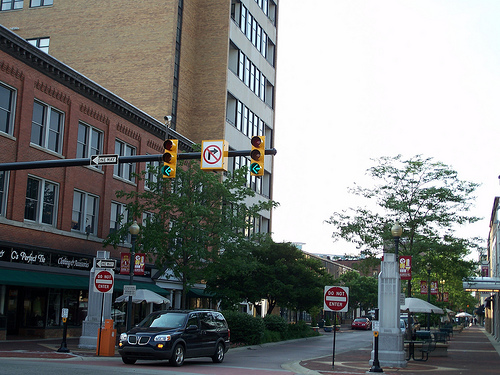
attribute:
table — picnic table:
[404, 337, 431, 364]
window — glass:
[113, 136, 123, 177]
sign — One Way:
[95, 151, 135, 172]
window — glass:
[0, 78, 20, 139]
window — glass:
[22, 87, 85, 151]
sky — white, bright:
[318, 53, 413, 139]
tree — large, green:
[324, 153, 485, 359]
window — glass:
[19, 169, 49, 226]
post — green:
[367, 332, 384, 372]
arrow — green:
[249, 161, 261, 175]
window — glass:
[112, 137, 120, 177]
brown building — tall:
[0, 0, 276, 313]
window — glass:
[77, 122, 104, 183]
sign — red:
[395, 255, 413, 280]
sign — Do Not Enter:
[320, 282, 352, 315]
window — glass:
[21, 165, 66, 225]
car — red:
[351, 313, 373, 330]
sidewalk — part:
[416, 307, 483, 358]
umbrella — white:
[114, 285, 166, 307]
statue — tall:
[368, 220, 408, 368]